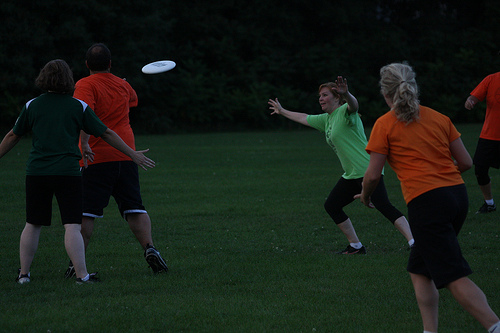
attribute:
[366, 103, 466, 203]
shirt — orange, short sleeved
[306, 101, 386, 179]
shirt — green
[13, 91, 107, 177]
shirt — dark green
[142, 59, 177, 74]
frisbee — white, plastic, flying, mid air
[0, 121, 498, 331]
grass — green, short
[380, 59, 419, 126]
hair — blonde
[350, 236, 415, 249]
socks — white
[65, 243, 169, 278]
shoes — black, white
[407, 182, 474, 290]
shorts — black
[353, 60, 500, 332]
lady — blonde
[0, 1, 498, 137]
trees — green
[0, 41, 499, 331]
people — playing